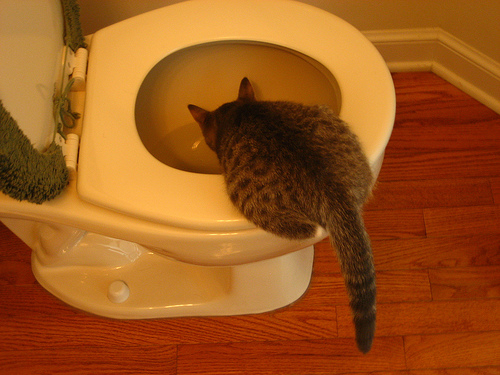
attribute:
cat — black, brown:
[187, 76, 377, 358]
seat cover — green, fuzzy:
[6, 113, 88, 207]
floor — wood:
[385, 212, 497, 372]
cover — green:
[4, 5, 95, 208]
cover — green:
[10, 163, 67, 192]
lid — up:
[0, 35, 125, 152]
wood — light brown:
[403, 144, 498, 313]